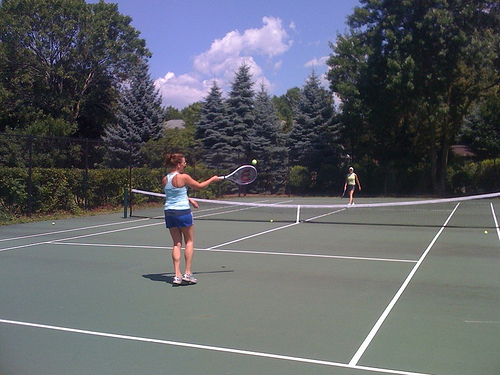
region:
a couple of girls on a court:
[57, 63, 497, 333]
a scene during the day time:
[6, 3, 494, 373]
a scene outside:
[10, 8, 485, 369]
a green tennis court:
[10, 2, 485, 369]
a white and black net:
[79, 162, 486, 269]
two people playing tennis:
[126, 106, 388, 318]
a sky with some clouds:
[77, 3, 415, 140]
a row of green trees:
[0, 3, 498, 207]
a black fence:
[3, 118, 318, 230]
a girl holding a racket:
[142, 129, 264, 284]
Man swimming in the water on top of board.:
[235, 340, 260, 351]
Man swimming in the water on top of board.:
[125, 302, 165, 324]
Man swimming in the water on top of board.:
[286, 153, 315, 168]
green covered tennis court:
[1, 190, 497, 373]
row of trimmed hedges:
[0, 163, 197, 208]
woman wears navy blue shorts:
[163, 209, 195, 229]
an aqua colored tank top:
[158, 169, 193, 210]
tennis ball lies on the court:
[482, 228, 492, 234]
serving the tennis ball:
[162, 152, 272, 284]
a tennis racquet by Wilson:
[216, 162, 257, 189]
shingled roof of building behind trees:
[158, 117, 190, 132]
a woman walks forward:
[335, 166, 363, 202]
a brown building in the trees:
[444, 141, 475, 168]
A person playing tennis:
[158, 147, 265, 294]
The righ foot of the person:
[181, 269, 198, 286]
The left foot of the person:
[170, 269, 185, 285]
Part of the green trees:
[23, 71, 65, 113]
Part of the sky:
[148, 15, 193, 33]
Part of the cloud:
[224, 43, 246, 50]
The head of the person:
[163, 148, 190, 170]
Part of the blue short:
[176, 214, 188, 219]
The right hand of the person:
[208, 173, 220, 185]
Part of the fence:
[23, 136, 44, 150]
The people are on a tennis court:
[5, 90, 496, 365]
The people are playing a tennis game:
[25, 98, 498, 369]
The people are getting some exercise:
[6, 118, 486, 363]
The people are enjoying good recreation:
[5, 140, 485, 355]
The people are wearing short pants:
[35, 110, 465, 370]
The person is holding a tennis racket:
[71, 115, 291, 348]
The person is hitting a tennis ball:
[90, 125, 301, 343]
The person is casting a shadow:
[97, 117, 292, 369]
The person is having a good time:
[93, 101, 301, 356]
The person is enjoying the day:
[107, 110, 312, 373]